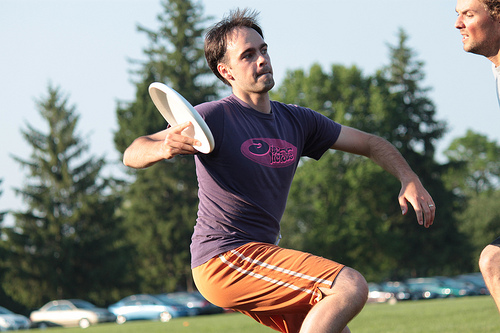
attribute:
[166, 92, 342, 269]
tee shirt — purple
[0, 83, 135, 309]
pine tree —  big,  green, pine 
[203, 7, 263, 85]
hair — brown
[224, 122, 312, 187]
logo — pink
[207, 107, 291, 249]
shirt — tee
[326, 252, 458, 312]
cars —  in line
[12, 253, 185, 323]
cars —  in line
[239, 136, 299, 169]
logo — pink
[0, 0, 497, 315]
trees — pine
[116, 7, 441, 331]
man — jumping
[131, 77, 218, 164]
frisbee — white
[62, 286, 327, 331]
car — blue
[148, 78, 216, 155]
disc — white, plastic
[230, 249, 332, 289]
stripe — white 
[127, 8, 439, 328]
male — blonde , white